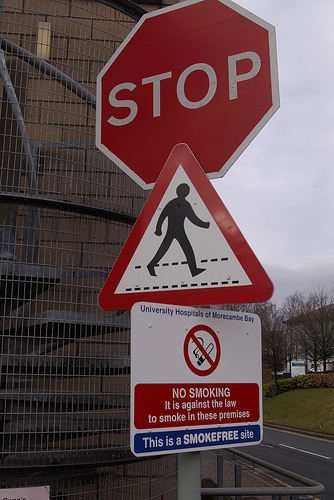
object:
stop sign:
[96, 1, 280, 194]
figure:
[146, 183, 211, 279]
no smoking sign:
[131, 301, 263, 457]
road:
[229, 424, 334, 500]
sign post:
[177, 452, 202, 500]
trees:
[260, 289, 287, 380]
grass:
[264, 384, 333, 435]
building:
[2, 1, 176, 500]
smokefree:
[182, 429, 243, 445]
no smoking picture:
[183, 324, 222, 377]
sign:
[96, 141, 275, 314]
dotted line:
[125, 278, 243, 295]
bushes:
[264, 373, 333, 400]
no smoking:
[171, 384, 232, 401]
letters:
[109, 49, 261, 127]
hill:
[263, 369, 333, 442]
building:
[272, 300, 333, 376]